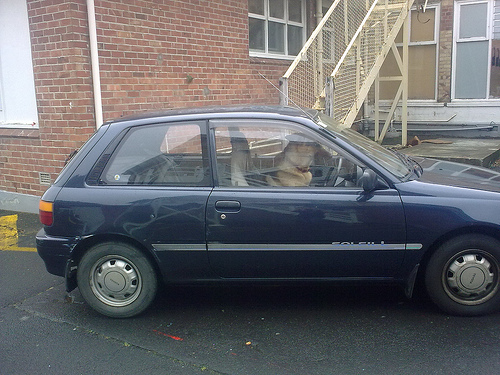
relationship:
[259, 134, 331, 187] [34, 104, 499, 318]
dog sitting in car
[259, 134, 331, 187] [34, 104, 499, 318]
german shepard sitting inside car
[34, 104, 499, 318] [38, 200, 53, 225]
car has tail light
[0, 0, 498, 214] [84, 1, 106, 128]
building has pipe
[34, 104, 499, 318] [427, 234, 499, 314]
vehicle has front tire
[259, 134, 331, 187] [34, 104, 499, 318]
dog waiting in car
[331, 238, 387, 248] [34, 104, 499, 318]
name fastened on side of car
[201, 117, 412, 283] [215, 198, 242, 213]
door has handle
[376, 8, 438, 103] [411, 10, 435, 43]
window covered by shade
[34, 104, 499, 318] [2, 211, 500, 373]
car parked on street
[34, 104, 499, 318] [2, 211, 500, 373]
car stopped on street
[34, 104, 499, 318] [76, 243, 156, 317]
car has back tire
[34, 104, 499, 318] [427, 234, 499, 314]
car has front tire